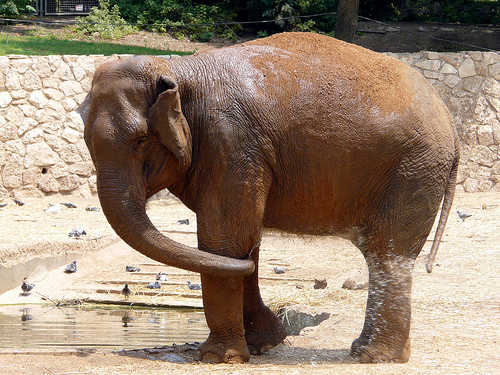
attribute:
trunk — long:
[96, 169, 256, 277]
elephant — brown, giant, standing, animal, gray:
[75, 31, 460, 364]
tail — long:
[423, 105, 461, 274]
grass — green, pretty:
[1, 28, 200, 56]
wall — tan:
[1, 49, 499, 207]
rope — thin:
[2, 10, 499, 50]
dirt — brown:
[238, 30, 409, 113]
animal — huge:
[74, 29, 463, 364]